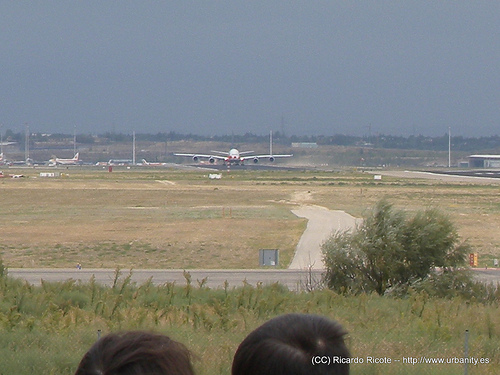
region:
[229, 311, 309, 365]
Man has black hair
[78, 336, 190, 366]
Man has brown hair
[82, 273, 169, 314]
Weed growing out of grass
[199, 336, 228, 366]
Green grass in field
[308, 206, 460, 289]
Green bushes in field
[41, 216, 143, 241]
Brown dirt in field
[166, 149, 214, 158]
Long wing of plane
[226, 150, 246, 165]
Front end of plane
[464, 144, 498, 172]
White house in field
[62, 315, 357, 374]
Men looking in field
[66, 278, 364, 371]
the back of two heads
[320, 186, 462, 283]
bush blowing in the wind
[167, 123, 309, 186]
a plane landing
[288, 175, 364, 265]
a small service road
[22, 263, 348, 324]
tall grass and weeds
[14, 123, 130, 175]
air planes at an airport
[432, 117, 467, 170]
a lamp post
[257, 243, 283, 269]
a grey electrical box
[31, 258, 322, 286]
a small road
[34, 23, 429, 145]
a hazy ski line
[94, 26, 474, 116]
the sky is dark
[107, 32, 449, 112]
the sky is gray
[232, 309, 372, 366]
a head of a toddler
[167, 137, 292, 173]
an airplane taking off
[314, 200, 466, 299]
a small tree is growing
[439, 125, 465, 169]
the pole is white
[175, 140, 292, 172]
the airplane is big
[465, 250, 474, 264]
the marker is red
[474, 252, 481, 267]
the marker is yellow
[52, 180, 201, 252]
the airfield is brown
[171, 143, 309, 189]
The plane is landing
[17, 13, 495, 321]
It is a desert.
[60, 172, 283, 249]
The ground is bare.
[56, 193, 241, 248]
The grass is dead.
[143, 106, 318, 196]
The plane is white.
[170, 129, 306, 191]
The plane is a commercial plane.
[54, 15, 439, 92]
The sky is clear and blue.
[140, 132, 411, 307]
The plane is landing on dirt.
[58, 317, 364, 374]
Two people ar watching the plane.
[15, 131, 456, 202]
There are many planes.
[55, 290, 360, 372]
two people's heads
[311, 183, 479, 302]
a tree to the right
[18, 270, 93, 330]
tall grass in front of the people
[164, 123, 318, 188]
an airplane in the background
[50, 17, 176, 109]
a dark grey sky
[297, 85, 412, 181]
a row of trees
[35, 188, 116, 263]
a field in front of the airplane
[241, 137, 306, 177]
part of an airplane wing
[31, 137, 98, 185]
an airplane to the left in the back